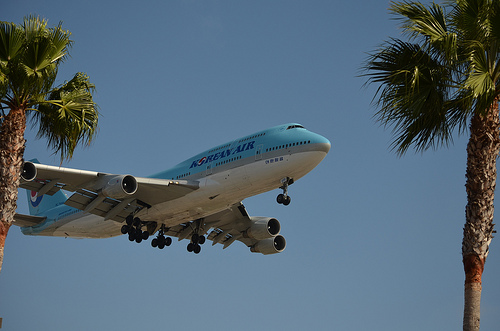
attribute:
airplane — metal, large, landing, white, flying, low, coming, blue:
[14, 119, 336, 257]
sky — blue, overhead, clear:
[4, 4, 500, 330]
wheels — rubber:
[272, 192, 295, 205]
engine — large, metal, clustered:
[98, 174, 141, 197]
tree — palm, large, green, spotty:
[0, 12, 100, 272]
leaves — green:
[22, 16, 49, 57]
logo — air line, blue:
[185, 135, 263, 174]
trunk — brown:
[0, 105, 27, 244]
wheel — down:
[189, 244, 200, 254]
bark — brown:
[9, 134, 22, 154]